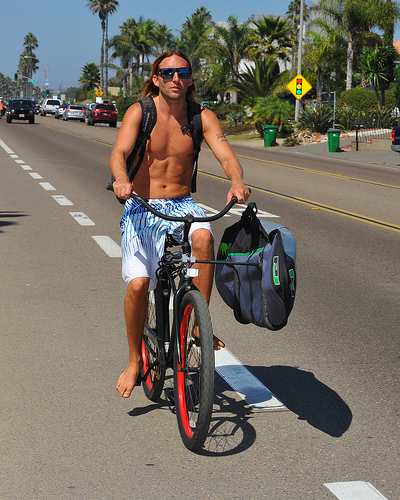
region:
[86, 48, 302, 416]
person on a bike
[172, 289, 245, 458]
front tire of bike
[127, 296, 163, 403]
rear tire on the bike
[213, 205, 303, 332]
bag on the bike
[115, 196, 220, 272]
shorts on the person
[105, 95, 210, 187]
straps to a backpack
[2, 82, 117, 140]
vehicles on the street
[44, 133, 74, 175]
lane for the traffic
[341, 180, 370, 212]
lane for the traffic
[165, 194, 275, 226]
lettering on the street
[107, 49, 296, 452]
Man without a shirt or shoes on riding bike.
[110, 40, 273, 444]
a shirtless guy on a bike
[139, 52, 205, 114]
the head of a shirtless guy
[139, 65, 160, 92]
the hair of a shirtless guy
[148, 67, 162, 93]
the ear of a shirtless guy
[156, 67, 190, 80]
the sunglasses of a shirtless guy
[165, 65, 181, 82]
the nose of a shirtless guy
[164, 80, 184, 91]
the mouth of a shirtless guy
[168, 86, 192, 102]
the chin of a shirtless guy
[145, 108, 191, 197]
the abs of a shirtless guy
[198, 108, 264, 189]
the arm of a shirtless guy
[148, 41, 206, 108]
head of a person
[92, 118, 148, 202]
arm of a person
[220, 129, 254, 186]
arm of a person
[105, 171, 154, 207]
hand of a person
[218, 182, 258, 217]
hand of a person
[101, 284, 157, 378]
leg of a person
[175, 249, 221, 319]
leg of a person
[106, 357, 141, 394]
feet of a person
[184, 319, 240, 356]
feet of a person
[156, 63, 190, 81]
eye of a person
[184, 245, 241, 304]
leg of a person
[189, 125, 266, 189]
arm of a person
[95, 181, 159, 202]
hand of a person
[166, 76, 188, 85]
nose of a person